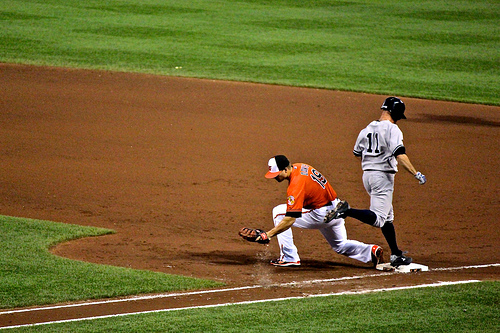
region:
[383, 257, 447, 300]
There is a white base here that is first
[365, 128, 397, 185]
The number on the back of this shirt is "11"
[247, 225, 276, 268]
There is a glove here that is great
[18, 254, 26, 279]
There is bright green grass that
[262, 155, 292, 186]
There is a hat here that is really lovely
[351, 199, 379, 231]
There are tall socks that this man is wearing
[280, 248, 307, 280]
There is a pair of shoes that are orange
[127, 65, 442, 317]
Jackson Mingus took this photo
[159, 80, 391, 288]
This photo was taken in the city of Cleveland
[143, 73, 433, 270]
This photo has a great deal of detail to it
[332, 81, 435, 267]
a baseball player running to a base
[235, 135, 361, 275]
a baseball player in an orange jersey catching a ball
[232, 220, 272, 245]
a baseball glove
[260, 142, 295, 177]
a baseball cap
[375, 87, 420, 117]
a black baseball helmet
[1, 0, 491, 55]
some green turf grass on the baseball field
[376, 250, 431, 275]
a baseball base on the field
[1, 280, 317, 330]
some white painted lines on the baseball field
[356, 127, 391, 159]
the number 11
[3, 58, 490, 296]
some dirt on the baseball field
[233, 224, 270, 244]
a brown baseball glove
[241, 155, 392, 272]
a baseball player in an orange shirt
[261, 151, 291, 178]
a black white and orange baseball cap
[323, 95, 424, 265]
a baseball player running to first base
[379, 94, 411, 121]
a black baseball helmet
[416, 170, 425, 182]
a pair of white baseball gloves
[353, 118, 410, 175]
a white baseball jersey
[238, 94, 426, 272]
a pair of people playing baseball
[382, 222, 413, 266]
a pair of black shoes and socks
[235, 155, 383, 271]
a baseball player in a bright orange jersey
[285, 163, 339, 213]
yellow and black jersey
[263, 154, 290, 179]
baseball cap on head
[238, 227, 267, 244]
black leather baseball mitt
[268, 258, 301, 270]
black and orange cleat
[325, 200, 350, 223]
black and white cleat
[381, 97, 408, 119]
black plastic batting helmet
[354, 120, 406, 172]
grey and black jersey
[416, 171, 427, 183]
white and blue batting gloves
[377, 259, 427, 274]
white padded baseball base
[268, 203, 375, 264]
white and orange pants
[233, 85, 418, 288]
two people playing baseball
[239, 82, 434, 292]
two men playing baseaball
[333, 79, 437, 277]
man running across base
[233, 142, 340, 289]
man playing first base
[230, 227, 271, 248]
brown and black baseball glove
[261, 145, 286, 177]
baseball hat on head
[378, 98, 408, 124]
black batters helmet on head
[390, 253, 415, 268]
black and white cleats on feet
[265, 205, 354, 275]
white and orange baseball pants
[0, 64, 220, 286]
brown dirt field with grass